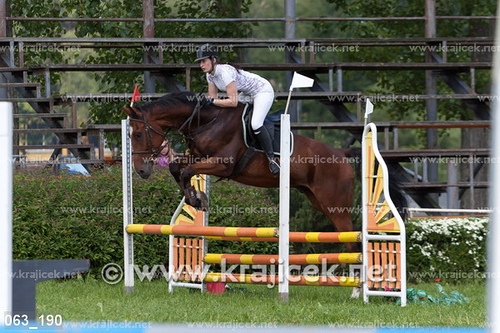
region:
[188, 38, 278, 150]
woman wearing a helmet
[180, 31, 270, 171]
woman wearing white shirt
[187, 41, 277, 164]
woman wearing white pants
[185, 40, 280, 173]
woman wearing black boots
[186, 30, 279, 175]
woman sitting on a horse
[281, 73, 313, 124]
flag on a pole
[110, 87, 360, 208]
horse jumps over obstacle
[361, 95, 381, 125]
flag on a pole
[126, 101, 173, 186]
face of a horse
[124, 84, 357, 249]
Dark brown horse with a black mane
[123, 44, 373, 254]
Woman and horse taking a jump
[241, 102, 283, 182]
English style leather saddle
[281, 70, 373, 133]
Two white flags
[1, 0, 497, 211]
Empty wooden bleachers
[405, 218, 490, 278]
Small hedge with white flowers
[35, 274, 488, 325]
Lawn with green grass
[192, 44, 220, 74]
Black riding helmet with a strap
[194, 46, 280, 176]
Woman wearing black and white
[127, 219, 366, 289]
Yellow and orange horizontal poles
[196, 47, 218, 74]
lady wearing black helmet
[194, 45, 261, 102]
one woman wearing light patterned short sleeved shirt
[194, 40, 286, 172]
one woman wearing white riding pants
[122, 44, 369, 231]
one woman riding brown horse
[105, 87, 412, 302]
one brown horse jumping over post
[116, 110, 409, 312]
orange and yellow horse jumping post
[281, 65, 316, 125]
one little white flag on thin stick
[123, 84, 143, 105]
one little red flag on thin stick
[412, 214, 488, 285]
little green hedge with white flowers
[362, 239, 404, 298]
little section of orange picket fencing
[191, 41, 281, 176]
woman riding a horse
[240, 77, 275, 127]
woman's pants are white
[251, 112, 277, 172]
woman is wearing boots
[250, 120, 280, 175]
woman's boots are black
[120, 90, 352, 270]
the horse is brown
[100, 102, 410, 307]
horse is jumping over obstacle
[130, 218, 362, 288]
poles are orange and yellow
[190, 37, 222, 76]
woman wearing a helmet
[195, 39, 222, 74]
helmet strapped to woman's face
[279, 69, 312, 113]
white flag on pole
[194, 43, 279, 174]
a female jockey riding a horse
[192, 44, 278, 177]
a woman wearing a black helmet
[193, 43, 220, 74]
a black helmet strapped on the woman's head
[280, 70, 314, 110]
a white flag on a pole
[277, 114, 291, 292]
a white pole holding a flag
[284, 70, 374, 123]
two white flags on poles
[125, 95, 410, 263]
a brown and black horse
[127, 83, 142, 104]
a red flag on a pole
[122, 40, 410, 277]
a jockey riding a horse jumping over the horizontal poles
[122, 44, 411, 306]
a woman riding a brown and black horse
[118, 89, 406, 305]
horse jumping a fence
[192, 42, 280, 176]
person wearing a black hat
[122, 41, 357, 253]
person on a horse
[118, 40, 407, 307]
rider jumping horse over fence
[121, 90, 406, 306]
horse jumping over orange and yellow fence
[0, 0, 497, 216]
empty bleachers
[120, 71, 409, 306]
fence with flags on the posts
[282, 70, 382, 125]
two white flags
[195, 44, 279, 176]
rider wearing black boots and gloves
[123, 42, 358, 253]
rider astride a brown horse with black mane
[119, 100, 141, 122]
Ears of a horse